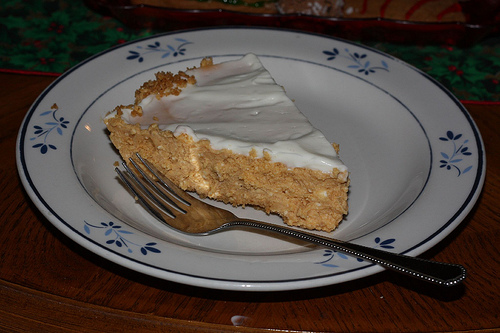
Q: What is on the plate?
A: Pie.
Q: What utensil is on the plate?
A: A fork.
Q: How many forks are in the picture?
A: One.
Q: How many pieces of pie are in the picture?
A: One.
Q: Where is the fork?
A: Beside the pie.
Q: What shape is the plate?
A: Round.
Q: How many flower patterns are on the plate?
A: Six.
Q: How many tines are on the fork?
A: Four.